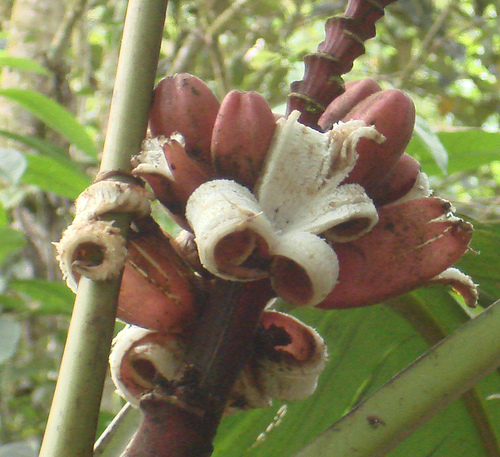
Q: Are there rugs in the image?
A: No, there are no rugs.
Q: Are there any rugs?
A: No, there are no rugs.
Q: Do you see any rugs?
A: No, there are no rugs.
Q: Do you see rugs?
A: No, there are no rugs.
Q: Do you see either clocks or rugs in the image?
A: No, there are no rugs or clocks.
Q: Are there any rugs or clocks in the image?
A: No, there are no rugs or clocks.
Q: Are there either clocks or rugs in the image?
A: No, there are no rugs or clocks.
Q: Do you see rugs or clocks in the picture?
A: No, there are no rugs or clocks.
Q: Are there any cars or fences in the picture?
A: No, there are no fences or cars.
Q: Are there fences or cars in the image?
A: No, there are no fences or cars.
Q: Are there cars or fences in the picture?
A: No, there are no fences or cars.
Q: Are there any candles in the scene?
A: No, there are no candles.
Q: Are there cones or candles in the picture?
A: No, there are no candles or cones.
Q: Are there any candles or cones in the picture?
A: No, there are no candles or cones.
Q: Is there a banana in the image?
A: Yes, there is a banana.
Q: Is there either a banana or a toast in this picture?
A: Yes, there is a banana.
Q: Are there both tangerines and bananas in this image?
A: No, there is a banana but no tangerines.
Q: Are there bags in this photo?
A: No, there are no bags.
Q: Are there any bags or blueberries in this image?
A: No, there are no bags or blueberries.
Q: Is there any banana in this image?
A: Yes, there is a banana.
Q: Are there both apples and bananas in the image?
A: No, there is a banana but no apples.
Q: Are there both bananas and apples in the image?
A: No, there is a banana but no apples.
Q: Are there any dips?
A: No, there are no dips.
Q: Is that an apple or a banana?
A: That is a banana.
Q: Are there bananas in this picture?
A: Yes, there is a banana.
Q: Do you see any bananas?
A: Yes, there is a banana.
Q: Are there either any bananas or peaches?
A: Yes, there is a banana.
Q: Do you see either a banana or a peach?
A: Yes, there is a banana.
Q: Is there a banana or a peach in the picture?
A: Yes, there is a banana.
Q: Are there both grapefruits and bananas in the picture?
A: No, there is a banana but no grapefruits.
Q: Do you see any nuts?
A: No, there are no nuts.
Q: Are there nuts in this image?
A: No, there are no nuts.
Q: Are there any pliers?
A: No, there are no pliers.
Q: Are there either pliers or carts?
A: No, there are no pliers or carts.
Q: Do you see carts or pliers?
A: No, there are no pliers or carts.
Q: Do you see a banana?
A: Yes, there is a banana.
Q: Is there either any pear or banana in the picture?
A: Yes, there is a banana.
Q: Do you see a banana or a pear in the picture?
A: Yes, there is a banana.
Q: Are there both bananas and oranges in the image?
A: No, there is a banana but no oranges.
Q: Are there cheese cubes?
A: No, there are no cheese cubes.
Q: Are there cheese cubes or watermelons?
A: No, there are no cheese cubes or watermelons.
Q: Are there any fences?
A: No, there are no fences.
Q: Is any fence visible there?
A: No, there are no fences.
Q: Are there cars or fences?
A: No, there are no fences or cars.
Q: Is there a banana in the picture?
A: Yes, there are bananas.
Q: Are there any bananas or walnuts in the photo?
A: Yes, there are bananas.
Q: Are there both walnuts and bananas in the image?
A: No, there are bananas but no walnuts.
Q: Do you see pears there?
A: No, there are no pears.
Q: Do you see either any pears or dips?
A: No, there are no pears or dips.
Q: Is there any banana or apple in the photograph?
A: Yes, there are bananas.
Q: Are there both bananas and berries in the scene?
A: No, there are bananas but no berries.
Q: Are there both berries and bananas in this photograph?
A: No, there are bananas but no berries.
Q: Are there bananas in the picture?
A: Yes, there are bananas.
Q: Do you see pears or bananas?
A: Yes, there are bananas.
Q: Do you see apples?
A: No, there are no apples.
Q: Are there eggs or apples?
A: No, there are no apples or eggs.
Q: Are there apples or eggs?
A: No, there are no apples or eggs.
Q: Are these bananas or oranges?
A: These are bananas.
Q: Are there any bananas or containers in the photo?
A: Yes, there is a banana.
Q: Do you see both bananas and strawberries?
A: No, there is a banana but no strawberries.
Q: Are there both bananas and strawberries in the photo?
A: No, there is a banana but no strawberries.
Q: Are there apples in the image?
A: No, there are no apples.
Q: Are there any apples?
A: No, there are no apples.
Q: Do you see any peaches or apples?
A: No, there are no apples or peaches.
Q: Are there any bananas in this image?
A: Yes, there is a banana.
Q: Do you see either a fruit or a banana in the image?
A: Yes, there is a banana.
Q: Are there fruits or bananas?
A: Yes, there is a banana.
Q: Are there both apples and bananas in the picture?
A: No, there is a banana but no apples.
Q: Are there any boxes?
A: No, there are no boxes.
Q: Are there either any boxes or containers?
A: No, there are no boxes or containers.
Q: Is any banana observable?
A: Yes, there is a banana.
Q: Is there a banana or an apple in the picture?
A: Yes, there is a banana.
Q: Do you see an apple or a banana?
A: Yes, there is a banana.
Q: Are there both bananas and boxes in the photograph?
A: No, there is a banana but no boxes.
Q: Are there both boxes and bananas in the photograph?
A: No, there is a banana but no boxes.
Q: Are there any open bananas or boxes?
A: Yes, there is an open banana.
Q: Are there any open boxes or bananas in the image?
A: Yes, there is an open banana.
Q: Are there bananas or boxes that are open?
A: Yes, the banana is open.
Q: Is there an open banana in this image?
A: Yes, there is an open banana.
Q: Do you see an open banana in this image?
A: Yes, there is an open banana.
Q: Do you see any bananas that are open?
A: Yes, there is a banana that is open.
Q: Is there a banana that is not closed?
A: Yes, there is a open banana.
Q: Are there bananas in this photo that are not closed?
A: Yes, there is a open banana.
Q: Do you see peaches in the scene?
A: No, there are no peaches.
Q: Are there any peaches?
A: No, there are no peaches.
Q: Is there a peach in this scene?
A: No, there are no peaches.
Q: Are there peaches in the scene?
A: No, there are no peaches.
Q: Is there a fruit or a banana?
A: Yes, there is a banana.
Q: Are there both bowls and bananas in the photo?
A: No, there is a banana but no bowls.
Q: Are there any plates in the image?
A: No, there are no plates.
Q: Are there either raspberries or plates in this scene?
A: No, there are no plates or raspberries.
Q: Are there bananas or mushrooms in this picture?
A: Yes, there is a banana.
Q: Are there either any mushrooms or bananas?
A: Yes, there is a banana.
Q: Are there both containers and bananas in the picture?
A: No, there is a banana but no containers.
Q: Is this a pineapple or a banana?
A: This is a banana.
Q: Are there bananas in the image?
A: Yes, there are bananas.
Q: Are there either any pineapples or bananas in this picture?
A: Yes, there are bananas.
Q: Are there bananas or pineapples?
A: Yes, there are bananas.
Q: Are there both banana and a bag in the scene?
A: No, there are bananas but no bags.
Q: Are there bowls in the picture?
A: No, there are no bowls.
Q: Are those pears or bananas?
A: Those are bananas.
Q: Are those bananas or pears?
A: Those are bananas.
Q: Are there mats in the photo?
A: No, there are no mats.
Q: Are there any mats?
A: No, there are no mats.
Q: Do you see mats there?
A: No, there are no mats.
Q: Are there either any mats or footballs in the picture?
A: No, there are no mats or footballs.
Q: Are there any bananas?
A: Yes, there are bananas.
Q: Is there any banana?
A: Yes, there are bananas.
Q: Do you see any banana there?
A: Yes, there are bananas.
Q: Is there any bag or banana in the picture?
A: Yes, there are bananas.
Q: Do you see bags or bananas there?
A: Yes, there are bananas.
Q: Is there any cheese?
A: No, there is no cheese.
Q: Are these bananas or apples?
A: These are bananas.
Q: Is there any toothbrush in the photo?
A: No, there are no toothbrushes.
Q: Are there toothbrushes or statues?
A: No, there are no toothbrushes or statues.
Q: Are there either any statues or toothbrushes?
A: No, there are no toothbrushes or statues.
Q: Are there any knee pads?
A: No, there are no knee pads.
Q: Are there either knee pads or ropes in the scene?
A: No, there are no knee pads or ropes.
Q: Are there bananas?
A: Yes, there are bananas.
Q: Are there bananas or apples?
A: Yes, there are bananas.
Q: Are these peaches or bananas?
A: These are bananas.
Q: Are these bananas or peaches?
A: These are bananas.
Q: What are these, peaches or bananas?
A: These are bananas.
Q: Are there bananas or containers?
A: Yes, there are bananas.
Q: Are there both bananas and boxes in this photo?
A: No, there are bananas but no boxes.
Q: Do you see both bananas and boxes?
A: No, there are bananas but no boxes.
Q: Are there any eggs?
A: No, there are no eggs.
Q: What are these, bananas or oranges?
A: These are bananas.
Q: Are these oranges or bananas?
A: These are bananas.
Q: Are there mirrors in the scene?
A: No, there are no mirrors.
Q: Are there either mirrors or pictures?
A: No, there are no mirrors or pictures.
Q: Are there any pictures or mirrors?
A: No, there are no mirrors or pictures.